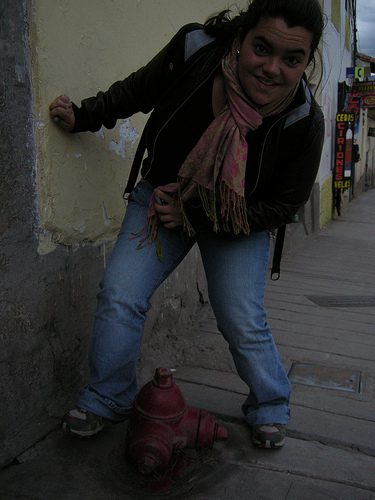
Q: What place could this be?
A: It is a sidewalk.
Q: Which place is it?
A: It is a sidewalk.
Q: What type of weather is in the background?
A: It is cloudy.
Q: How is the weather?
A: It is cloudy.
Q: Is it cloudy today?
A: Yes, it is cloudy.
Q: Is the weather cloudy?
A: Yes, it is cloudy.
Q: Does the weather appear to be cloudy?
A: Yes, it is cloudy.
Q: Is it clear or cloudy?
A: It is cloudy.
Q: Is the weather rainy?
A: No, it is cloudy.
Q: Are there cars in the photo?
A: No, there are no cars.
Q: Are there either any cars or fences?
A: No, there are no cars or fences.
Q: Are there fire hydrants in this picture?
A: Yes, there is a fire hydrant.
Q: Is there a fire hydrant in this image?
A: Yes, there is a fire hydrant.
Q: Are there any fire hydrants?
A: Yes, there is a fire hydrant.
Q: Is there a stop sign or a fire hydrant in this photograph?
A: Yes, there is a fire hydrant.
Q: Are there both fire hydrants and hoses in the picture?
A: No, there is a fire hydrant but no hoses.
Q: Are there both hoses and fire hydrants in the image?
A: No, there is a fire hydrant but no hoses.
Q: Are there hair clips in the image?
A: No, there are no hair clips.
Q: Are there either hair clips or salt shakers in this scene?
A: No, there are no hair clips or salt shakers.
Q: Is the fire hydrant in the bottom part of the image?
A: Yes, the fire hydrant is in the bottom of the image.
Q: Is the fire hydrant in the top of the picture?
A: No, the fire hydrant is in the bottom of the image.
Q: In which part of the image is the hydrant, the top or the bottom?
A: The hydrant is in the bottom of the image.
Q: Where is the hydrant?
A: The hydrant is on the sidewalk.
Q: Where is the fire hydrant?
A: The hydrant is on the sidewalk.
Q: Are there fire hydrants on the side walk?
A: Yes, there is a fire hydrant on the side walk.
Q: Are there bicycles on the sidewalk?
A: No, there is a fire hydrant on the sidewalk.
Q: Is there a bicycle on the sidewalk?
A: No, there is a fire hydrant on the sidewalk.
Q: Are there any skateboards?
A: No, there are no skateboards.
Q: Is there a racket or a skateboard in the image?
A: No, there are no skateboards or rackets.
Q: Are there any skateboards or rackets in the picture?
A: No, there are no skateboards or rackets.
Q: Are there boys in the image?
A: No, there are no boys.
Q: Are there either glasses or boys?
A: No, there are no boys or glasses.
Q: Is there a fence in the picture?
A: No, there are no fences.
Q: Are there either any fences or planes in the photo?
A: No, there are no fences or planes.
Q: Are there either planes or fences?
A: No, there are no fences or planes.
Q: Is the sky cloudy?
A: Yes, the sky is cloudy.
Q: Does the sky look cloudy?
A: Yes, the sky is cloudy.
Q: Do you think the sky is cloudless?
A: No, the sky is cloudy.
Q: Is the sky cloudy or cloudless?
A: The sky is cloudy.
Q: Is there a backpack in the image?
A: Yes, there is a backpack.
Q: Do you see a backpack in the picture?
A: Yes, there is a backpack.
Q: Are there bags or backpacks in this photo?
A: Yes, there is a backpack.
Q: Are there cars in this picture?
A: No, there are no cars.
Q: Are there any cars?
A: No, there are no cars.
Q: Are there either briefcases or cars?
A: No, there are no cars or briefcases.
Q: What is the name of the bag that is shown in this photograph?
A: The bag is a backpack.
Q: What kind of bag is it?
A: The bag is a backpack.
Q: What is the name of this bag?
A: This is a backpack.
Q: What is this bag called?
A: This is a backpack.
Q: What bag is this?
A: This is a backpack.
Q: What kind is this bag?
A: This is a backpack.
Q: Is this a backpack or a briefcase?
A: This is a backpack.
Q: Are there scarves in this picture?
A: Yes, there is a scarf.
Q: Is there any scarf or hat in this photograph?
A: Yes, there is a scarf.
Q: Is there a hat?
A: No, there are no hats.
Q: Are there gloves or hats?
A: No, there are no hats or gloves.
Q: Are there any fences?
A: No, there are no fences.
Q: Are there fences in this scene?
A: No, there are no fences.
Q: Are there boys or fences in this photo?
A: No, there are no fences or boys.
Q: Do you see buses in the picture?
A: No, there are no buses.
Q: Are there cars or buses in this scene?
A: No, there are no buses or cars.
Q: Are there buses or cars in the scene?
A: No, there are no buses or cars.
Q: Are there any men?
A: No, there are no men.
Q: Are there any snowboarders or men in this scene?
A: No, there are no men or snowboarders.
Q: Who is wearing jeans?
A: The lady is wearing jeans.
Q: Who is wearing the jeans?
A: The lady is wearing jeans.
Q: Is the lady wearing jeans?
A: Yes, the lady is wearing jeans.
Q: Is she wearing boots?
A: No, the lady is wearing jeans.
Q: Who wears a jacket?
A: The lady wears a jacket.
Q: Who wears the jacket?
A: The lady wears a jacket.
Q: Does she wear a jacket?
A: Yes, the lady wears a jacket.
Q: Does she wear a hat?
A: No, the lady wears a jacket.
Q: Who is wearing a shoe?
A: The lady is wearing a shoe.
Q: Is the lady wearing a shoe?
A: Yes, the lady is wearing a shoe.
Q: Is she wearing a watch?
A: No, the lady is wearing a shoe.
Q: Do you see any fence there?
A: No, there are no fences.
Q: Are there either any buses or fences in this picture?
A: No, there are no fences or buses.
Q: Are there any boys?
A: No, there are no boys.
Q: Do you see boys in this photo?
A: No, there are no boys.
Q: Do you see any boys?
A: No, there are no boys.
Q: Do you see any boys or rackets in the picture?
A: No, there are no boys or rackets.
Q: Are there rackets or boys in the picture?
A: No, there are no boys or rackets.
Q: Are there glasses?
A: No, there are no glasses.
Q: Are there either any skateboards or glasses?
A: No, there are no glasses or skateboards.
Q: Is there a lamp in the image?
A: No, there are no lamps.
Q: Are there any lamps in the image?
A: No, there are no lamps.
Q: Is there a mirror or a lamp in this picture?
A: No, there are no lamps or mirrors.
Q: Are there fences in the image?
A: No, there are no fences.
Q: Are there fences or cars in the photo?
A: No, there are no fences or cars.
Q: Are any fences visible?
A: No, there are no fences.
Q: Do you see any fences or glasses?
A: No, there are no fences or glasses.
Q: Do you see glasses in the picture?
A: No, there are no glasses.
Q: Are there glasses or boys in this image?
A: No, there are no glasses or boys.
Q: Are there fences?
A: No, there are no fences.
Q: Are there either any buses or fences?
A: No, there are no fences or buses.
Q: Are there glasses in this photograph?
A: No, there are no glasses.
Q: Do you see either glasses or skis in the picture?
A: No, there are no glasses or skis.